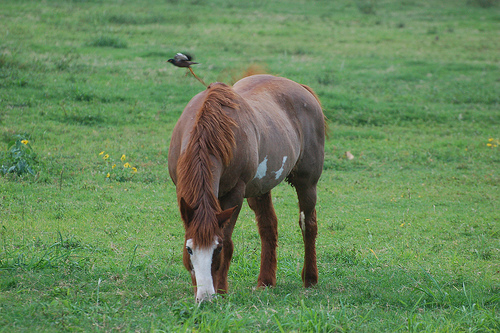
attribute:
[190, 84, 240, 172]
mane — brown, shaggy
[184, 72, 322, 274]
horse — standing, brown, alone, feeding, grazing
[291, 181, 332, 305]
leg — back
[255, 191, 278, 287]
leg — back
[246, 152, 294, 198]
stomach — white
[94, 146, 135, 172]
flowers — yellow, growing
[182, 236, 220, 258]
eyes — dark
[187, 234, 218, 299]
face — white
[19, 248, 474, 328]
grass — lush, green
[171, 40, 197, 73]
bird — flying, alone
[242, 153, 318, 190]
spots — white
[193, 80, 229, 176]
fur — in line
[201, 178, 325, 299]
legs — strong, back, brown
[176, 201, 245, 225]
ears — apart, alert, brown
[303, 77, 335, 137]
tail — brown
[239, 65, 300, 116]
back — brown